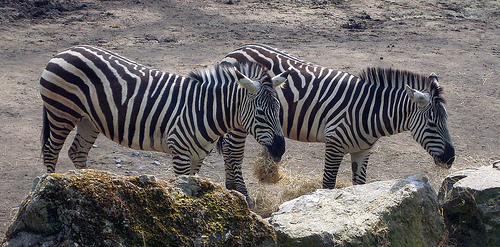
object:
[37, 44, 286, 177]
zebra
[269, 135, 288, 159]
nose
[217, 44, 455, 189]
zebra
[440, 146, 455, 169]
nose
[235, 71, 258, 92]
ear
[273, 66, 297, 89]
ear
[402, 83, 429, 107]
ear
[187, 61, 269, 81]
mane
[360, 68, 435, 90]
mane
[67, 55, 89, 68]
stripe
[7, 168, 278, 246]
rock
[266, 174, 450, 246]
rock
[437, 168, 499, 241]
rock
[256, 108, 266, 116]
eye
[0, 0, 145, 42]
dirt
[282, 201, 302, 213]
sunlight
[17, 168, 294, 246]
moss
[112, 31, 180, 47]
track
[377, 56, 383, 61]
pebble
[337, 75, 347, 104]
stripe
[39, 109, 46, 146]
hair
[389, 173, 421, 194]
shadow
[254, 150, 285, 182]
hay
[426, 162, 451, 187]
hay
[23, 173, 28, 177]
pebble